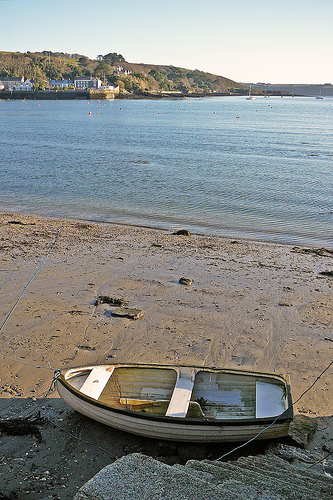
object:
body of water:
[1, 98, 333, 236]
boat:
[52, 362, 293, 445]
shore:
[0, 210, 333, 450]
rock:
[105, 302, 139, 320]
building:
[19, 79, 36, 91]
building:
[2, 77, 24, 92]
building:
[50, 76, 75, 91]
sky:
[1, 1, 333, 93]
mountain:
[0, 51, 281, 99]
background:
[1, 1, 333, 107]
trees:
[40, 61, 65, 79]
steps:
[69, 447, 333, 500]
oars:
[121, 395, 204, 414]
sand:
[0, 210, 332, 468]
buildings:
[1, 73, 123, 95]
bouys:
[0, 0, 332, 499]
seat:
[165, 373, 200, 417]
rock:
[177, 274, 198, 288]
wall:
[2, 90, 115, 101]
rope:
[0, 224, 65, 338]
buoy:
[87, 113, 94, 118]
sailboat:
[244, 86, 262, 102]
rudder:
[189, 396, 221, 424]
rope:
[10, 368, 120, 462]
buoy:
[210, 107, 221, 119]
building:
[96, 54, 106, 64]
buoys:
[7, 97, 21, 108]